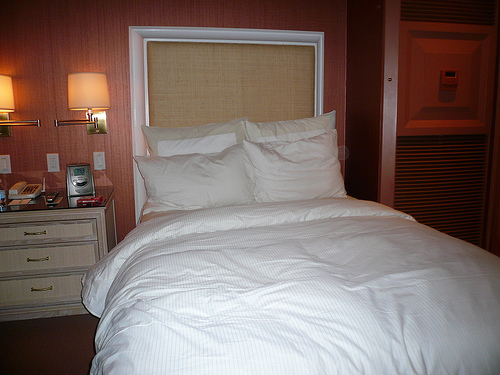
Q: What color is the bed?
A: White.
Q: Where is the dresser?
A: Left of bed.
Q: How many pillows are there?
A: 4.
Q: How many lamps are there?
A: 2.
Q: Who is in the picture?
A: No one.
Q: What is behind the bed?
A: Headboard.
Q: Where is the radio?
A: Dresser.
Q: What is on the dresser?
A: Phone.